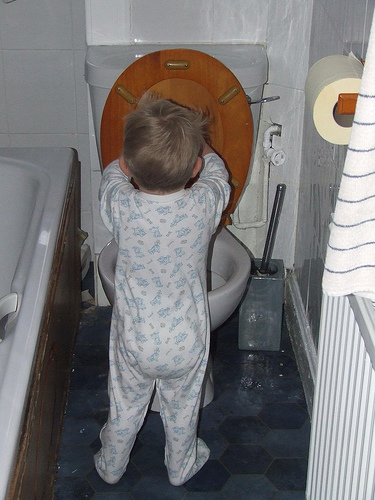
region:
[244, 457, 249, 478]
part of a floor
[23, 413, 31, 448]
part of a bath tab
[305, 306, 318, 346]
edge of a wall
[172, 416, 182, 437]
part of a cloth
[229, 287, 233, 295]
part of a toilet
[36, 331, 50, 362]
edge of a tab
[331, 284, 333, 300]
part of a towel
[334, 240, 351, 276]
edge of a towel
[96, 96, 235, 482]
baby standing in front of toilet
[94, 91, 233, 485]
baby in white and blue pajamas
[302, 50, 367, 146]
yellowish toilet paper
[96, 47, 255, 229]
wooden toilet seat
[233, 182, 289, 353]
metal toilet plunger next to the toilet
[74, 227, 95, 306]
tape peeling off the side of the bathtub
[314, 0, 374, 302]
gray and white striped towel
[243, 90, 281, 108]
metal toilet flushing handle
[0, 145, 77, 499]
large white and brown bathtub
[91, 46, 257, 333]
toilet with the lid open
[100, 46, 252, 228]
a wooden toilet seat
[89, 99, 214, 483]
young boy in front of a toilet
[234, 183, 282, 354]
a metal toilet bowl cleaner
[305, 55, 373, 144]
a roll of toilet paper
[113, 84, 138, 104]
stopper on a toilet seat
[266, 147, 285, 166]
the knob on a pipe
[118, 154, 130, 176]
a child's ear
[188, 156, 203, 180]
the ear of a child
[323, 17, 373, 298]
a blue and white towel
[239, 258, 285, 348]
a metal box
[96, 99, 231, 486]
The child is standing in front of the toilet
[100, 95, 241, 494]
The child has short brown hair and is wearing footie pajamas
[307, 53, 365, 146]
Full roll of toilet paper on wall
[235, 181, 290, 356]
Toilet brush and holder next to toilet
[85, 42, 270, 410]
White toilet bowl with two brown lids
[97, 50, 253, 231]
Both brown lids are up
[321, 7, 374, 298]
White towel with blue stripes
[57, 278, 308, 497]
Blue octagonal tiles on floor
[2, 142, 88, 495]
White bathtub with brown wood base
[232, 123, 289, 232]
White cutoff pipes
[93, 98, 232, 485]
A toddler in a onesie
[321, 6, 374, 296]
part of a white and blue stripped towel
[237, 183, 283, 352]
A gray toilet brush and holder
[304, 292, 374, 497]
Part of a white radiator heater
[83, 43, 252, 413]
A toilet with a baby in front of it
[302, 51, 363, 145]
A wooden toilet paper holder with toilet paper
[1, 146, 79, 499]
Part of a bathroom tub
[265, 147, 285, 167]
Water shut off knob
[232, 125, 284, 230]
Part of the water plumbing for a toilet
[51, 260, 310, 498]
A blue hexigon tiled floor